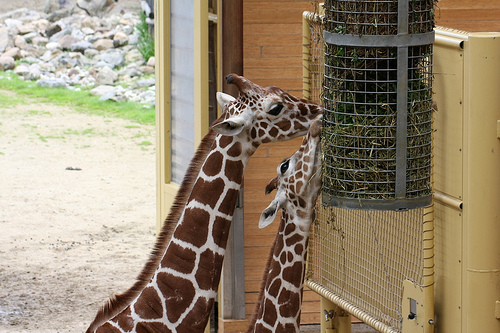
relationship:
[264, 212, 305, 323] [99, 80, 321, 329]
neck of giraffe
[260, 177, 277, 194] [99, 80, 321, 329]
right ear of giraffe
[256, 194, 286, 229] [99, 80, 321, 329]
ear of a giraffe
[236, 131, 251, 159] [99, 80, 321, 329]
white area of giraffe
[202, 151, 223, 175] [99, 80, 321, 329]
brown part of giraffe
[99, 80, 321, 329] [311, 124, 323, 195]
giraffe has a jaw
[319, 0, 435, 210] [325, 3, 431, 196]
basket has grass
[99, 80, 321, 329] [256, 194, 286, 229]
giraffe has ear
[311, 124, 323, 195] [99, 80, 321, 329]
jaw of giraffe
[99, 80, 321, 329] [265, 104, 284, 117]
giraffe has a right eye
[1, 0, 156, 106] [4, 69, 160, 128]
rocks near grass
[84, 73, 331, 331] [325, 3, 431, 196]
giraffes eating grass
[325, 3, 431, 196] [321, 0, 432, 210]
grass in feeder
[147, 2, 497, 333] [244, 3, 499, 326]
building made with wood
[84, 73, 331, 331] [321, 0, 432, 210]
giraffes eat from basket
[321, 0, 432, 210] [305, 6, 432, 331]
basket attached to fence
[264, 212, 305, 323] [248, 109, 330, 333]
neck of giraffe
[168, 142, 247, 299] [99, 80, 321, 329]
neck of giraffe